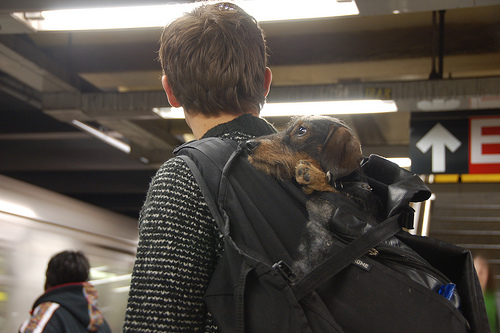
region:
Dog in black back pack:
[251, 115, 485, 331]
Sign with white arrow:
[404, 105, 499, 183]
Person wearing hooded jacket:
[20, 245, 122, 332]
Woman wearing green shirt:
[473, 246, 498, 329]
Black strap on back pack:
[282, 216, 415, 300]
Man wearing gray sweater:
[122, 0, 352, 332]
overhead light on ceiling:
[10, 0, 375, 38]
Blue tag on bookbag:
[426, 275, 463, 305]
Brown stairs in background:
[430, 182, 498, 277]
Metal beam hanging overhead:
[260, 70, 486, 122]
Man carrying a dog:
[104, 1, 482, 331]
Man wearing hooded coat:
[16, 236, 121, 331]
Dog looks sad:
[231, 93, 373, 203]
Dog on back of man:
[237, 102, 377, 214]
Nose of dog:
[236, 130, 268, 160]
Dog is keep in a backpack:
[188, 99, 488, 331]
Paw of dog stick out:
[285, 151, 332, 202]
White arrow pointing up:
[410, 114, 465, 178]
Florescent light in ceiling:
[7, 1, 377, 37]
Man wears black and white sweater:
[104, 1, 351, 325]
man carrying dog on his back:
[145, 22, 447, 312]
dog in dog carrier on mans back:
[257, 70, 434, 295]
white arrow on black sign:
[407, 104, 498, 189]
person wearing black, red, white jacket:
[20, 222, 108, 323]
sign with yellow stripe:
[408, 85, 495, 179]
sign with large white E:
[418, 94, 498, 186]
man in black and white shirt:
[142, 5, 283, 325]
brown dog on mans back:
[248, 58, 389, 220]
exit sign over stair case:
[400, 94, 498, 274]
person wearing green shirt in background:
[452, 237, 497, 312]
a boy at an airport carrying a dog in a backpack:
[89, 2, 497, 329]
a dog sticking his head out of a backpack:
[242, 117, 362, 179]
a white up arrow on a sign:
[416, 117, 464, 173]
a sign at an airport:
[409, 107, 498, 182]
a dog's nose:
[243, 139, 260, 150]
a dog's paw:
[294, 160, 311, 187]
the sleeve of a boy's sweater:
[142, 175, 192, 319]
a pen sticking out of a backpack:
[436, 279, 455, 301]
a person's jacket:
[22, 283, 113, 331]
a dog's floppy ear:
[320, 123, 365, 180]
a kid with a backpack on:
[119, 5, 498, 325]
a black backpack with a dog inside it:
[165, 110, 499, 326]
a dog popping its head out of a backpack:
[233, 101, 390, 189]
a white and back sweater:
[102, 125, 323, 325]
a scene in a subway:
[12, 0, 494, 328]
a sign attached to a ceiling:
[390, 102, 498, 187]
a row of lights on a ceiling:
[12, 5, 428, 155]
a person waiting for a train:
[18, 239, 163, 329]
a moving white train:
[4, 168, 147, 330]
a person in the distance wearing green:
[447, 242, 498, 327]